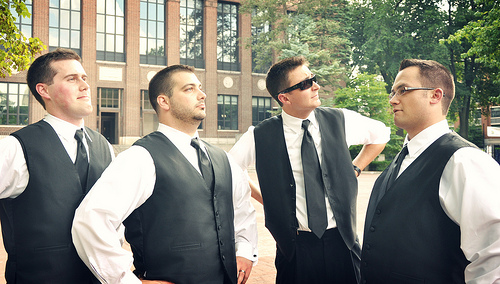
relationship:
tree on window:
[249, 3, 353, 103] [183, 0, 242, 67]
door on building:
[93, 105, 121, 150] [2, 2, 352, 138]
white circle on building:
[258, 79, 266, 89] [0, 0, 294, 147]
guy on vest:
[0, 47, 121, 283] [2, 117, 140, 282]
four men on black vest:
[30, 70, 459, 258] [141, 137, 252, 280]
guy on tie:
[228, 58, 393, 283] [298, 121, 319, 171]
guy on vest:
[228, 58, 393, 283] [319, 125, 346, 194]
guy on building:
[68, 60, 260, 282] [2, 2, 352, 163]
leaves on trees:
[237, 0, 499, 170] [239, 0, 499, 171]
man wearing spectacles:
[359, 61, 485, 277] [391, 80, 438, 100]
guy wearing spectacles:
[228, 58, 393, 283] [277, 72, 319, 93]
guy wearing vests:
[68, 64, 260, 283] [9, 117, 462, 252]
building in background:
[2, 2, 352, 163] [19, 4, 476, 101]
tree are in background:
[246, 0, 499, 172] [19, 4, 476, 101]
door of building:
[96, 87, 121, 144] [2, 2, 352, 138]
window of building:
[138, 0, 172, 67] [0, 0, 353, 164]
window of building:
[94, 0, 125, 67] [0, 0, 353, 164]